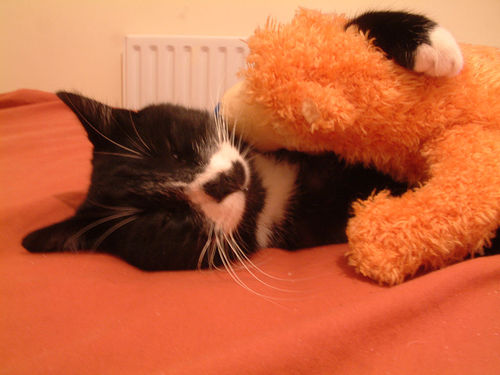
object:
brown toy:
[213, 5, 500, 288]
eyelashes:
[82, 149, 145, 161]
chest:
[249, 149, 301, 249]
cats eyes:
[166, 140, 197, 165]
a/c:
[123, 35, 250, 116]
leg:
[340, 6, 465, 81]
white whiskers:
[105, 128, 152, 229]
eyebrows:
[86, 194, 141, 253]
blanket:
[0, 85, 499, 374]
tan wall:
[3, 3, 498, 108]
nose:
[201, 171, 239, 205]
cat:
[17, 4, 499, 310]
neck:
[225, 113, 314, 246]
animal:
[211, 3, 500, 288]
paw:
[401, 20, 464, 80]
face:
[93, 100, 257, 260]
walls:
[16, 21, 92, 61]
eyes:
[152, 194, 187, 233]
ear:
[19, 215, 100, 255]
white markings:
[188, 142, 250, 235]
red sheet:
[8, 272, 170, 337]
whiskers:
[191, 222, 315, 316]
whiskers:
[200, 83, 271, 163]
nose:
[211, 100, 223, 117]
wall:
[10, 6, 239, 67]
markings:
[250, 142, 301, 249]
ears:
[53, 88, 130, 144]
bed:
[0, 280, 498, 372]